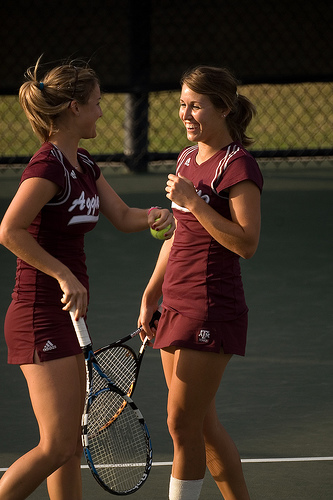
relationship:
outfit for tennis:
[1, 138, 104, 370] [5, 2, 332, 498]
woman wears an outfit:
[2, 59, 173, 499] [1, 138, 104, 370]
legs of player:
[159, 349, 258, 499] [138, 64, 264, 497]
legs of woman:
[2, 351, 93, 498] [2, 59, 173, 499]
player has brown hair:
[138, 64, 264, 497] [182, 61, 257, 147]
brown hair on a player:
[182, 61, 257, 147] [138, 64, 264, 497]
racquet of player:
[86, 323, 151, 438] [138, 64, 264, 497]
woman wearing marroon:
[0, 59, 176, 499] [151, 146, 255, 347]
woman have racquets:
[0, 59, 176, 499] [69, 310, 156, 497]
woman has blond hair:
[2, 59, 173, 499] [18, 58, 100, 140]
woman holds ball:
[2, 59, 173, 499] [148, 216, 172, 241]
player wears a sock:
[138, 64, 264, 497] [169, 476, 205, 499]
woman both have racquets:
[0, 59, 176, 499] [69, 310, 156, 497]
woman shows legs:
[2, 59, 173, 499] [2, 351, 93, 498]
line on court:
[1, 456, 332, 474] [1, 166, 332, 500]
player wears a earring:
[138, 64, 264, 497] [220, 113, 225, 119]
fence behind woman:
[1, 0, 332, 171] [0, 59, 176, 499]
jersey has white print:
[1, 138, 104, 370] [51, 147, 107, 223]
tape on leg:
[169, 476, 205, 499] [159, 349, 258, 499]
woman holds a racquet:
[2, 59, 173, 499] [69, 312, 153, 494]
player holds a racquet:
[138, 64, 264, 497] [86, 323, 151, 438]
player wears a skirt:
[138, 64, 264, 497] [151, 307, 252, 353]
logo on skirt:
[44, 338, 60, 357] [1, 312, 87, 366]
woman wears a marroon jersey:
[2, 59, 173, 499] [10, 140, 98, 293]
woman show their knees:
[0, 59, 176, 499] [40, 406, 198, 459]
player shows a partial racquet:
[138, 64, 264, 497] [86, 323, 151, 438]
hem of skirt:
[7, 347, 85, 368] [1, 312, 87, 366]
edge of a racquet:
[81, 399, 95, 496] [69, 312, 153, 494]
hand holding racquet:
[137, 297, 161, 345] [86, 323, 151, 438]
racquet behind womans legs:
[86, 323, 151, 438] [2, 351, 93, 498]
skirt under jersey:
[1, 312, 87, 366] [10, 140, 98, 293]